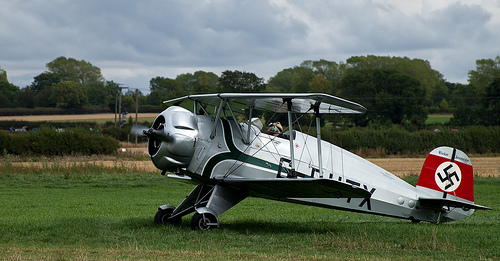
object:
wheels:
[189, 212, 218, 232]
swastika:
[439, 158, 461, 195]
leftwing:
[213, 177, 373, 200]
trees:
[445, 58, 500, 127]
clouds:
[0, 0, 499, 98]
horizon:
[0, 110, 499, 120]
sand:
[0, 158, 499, 178]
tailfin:
[415, 145, 476, 204]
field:
[0, 112, 499, 260]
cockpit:
[244, 117, 296, 141]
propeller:
[140, 115, 165, 159]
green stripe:
[199, 116, 312, 179]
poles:
[113, 93, 118, 127]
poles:
[133, 88, 139, 147]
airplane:
[141, 92, 497, 235]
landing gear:
[154, 184, 250, 232]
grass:
[1, 161, 500, 261]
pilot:
[265, 120, 284, 137]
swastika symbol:
[432, 160, 463, 194]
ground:
[4, 146, 499, 261]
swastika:
[432, 161, 463, 193]